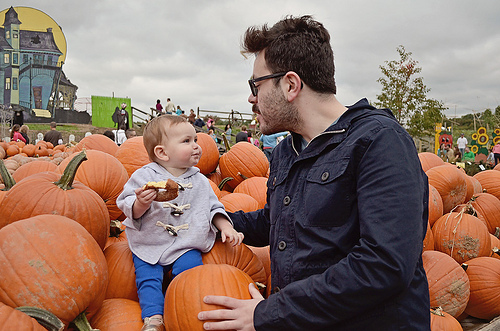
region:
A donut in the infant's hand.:
[132, 178, 178, 200]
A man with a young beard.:
[197, 14, 430, 329]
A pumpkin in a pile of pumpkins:
[0, 213, 109, 329]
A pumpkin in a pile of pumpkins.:
[162, 262, 259, 329]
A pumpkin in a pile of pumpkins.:
[421, 250, 470, 319]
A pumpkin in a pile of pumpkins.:
[217, 132, 268, 189]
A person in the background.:
[43, 121, 63, 146]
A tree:
[369, 44, 460, 141]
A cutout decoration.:
[0, 6, 92, 123]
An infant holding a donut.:
[115, 113, 245, 329]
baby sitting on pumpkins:
[93, 99, 234, 313]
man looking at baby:
[181, 15, 347, 193]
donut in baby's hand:
[139, 174, 196, 214]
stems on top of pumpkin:
[56, 142, 96, 198]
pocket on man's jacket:
[299, 151, 354, 221]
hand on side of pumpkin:
[211, 279, 267, 327]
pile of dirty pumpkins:
[423, 177, 491, 302]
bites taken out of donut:
[139, 174, 173, 194]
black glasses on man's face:
[241, 65, 289, 101]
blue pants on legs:
[126, 250, 196, 319]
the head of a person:
[9, 118, 21, 132]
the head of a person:
[18, 121, 31, 133]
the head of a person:
[47, 116, 60, 131]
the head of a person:
[144, 113, 202, 178]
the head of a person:
[228, 8, 333, 136]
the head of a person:
[116, 122, 131, 133]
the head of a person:
[151, 96, 162, 103]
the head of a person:
[163, 95, 173, 102]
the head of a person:
[456, 130, 468, 139]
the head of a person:
[189, 106, 195, 112]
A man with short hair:
[230, 20, 352, 178]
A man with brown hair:
[232, 5, 402, 162]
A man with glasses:
[215, 11, 385, 187]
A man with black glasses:
[233, 16, 377, 149]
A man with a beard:
[219, 18, 367, 189]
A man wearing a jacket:
[222, 18, 439, 322]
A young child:
[99, 106, 258, 309]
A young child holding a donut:
[92, 95, 258, 328]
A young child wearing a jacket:
[92, 99, 237, 328]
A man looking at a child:
[96, 16, 425, 293]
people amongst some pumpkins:
[23, 15, 476, 320]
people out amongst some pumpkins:
[4, 6, 470, 326]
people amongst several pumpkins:
[39, 20, 477, 319]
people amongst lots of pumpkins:
[13, 16, 476, 309]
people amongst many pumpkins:
[32, 17, 479, 322]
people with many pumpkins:
[17, 8, 482, 317]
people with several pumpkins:
[31, 27, 468, 315]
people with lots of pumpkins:
[50, 13, 467, 322]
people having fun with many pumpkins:
[15, 0, 482, 320]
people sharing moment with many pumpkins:
[25, 11, 465, 318]